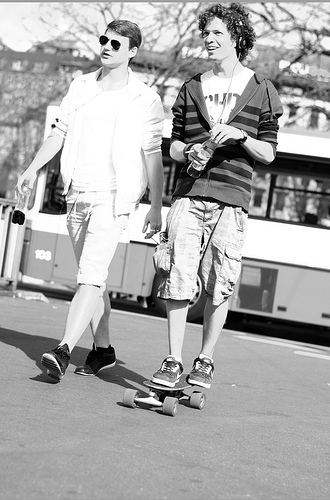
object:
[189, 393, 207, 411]
wheel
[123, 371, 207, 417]
skateboard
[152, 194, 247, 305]
shorts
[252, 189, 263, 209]
window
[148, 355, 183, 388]
shoe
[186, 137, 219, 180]
bottle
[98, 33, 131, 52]
glasses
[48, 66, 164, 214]
clothes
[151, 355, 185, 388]
left foot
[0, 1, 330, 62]
sky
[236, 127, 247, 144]
wrist watch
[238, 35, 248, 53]
headphones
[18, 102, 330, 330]
bus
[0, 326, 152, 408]
shadow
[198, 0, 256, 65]
hair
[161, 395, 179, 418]
wheels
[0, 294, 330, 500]
street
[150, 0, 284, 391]
boy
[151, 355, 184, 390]
right foot